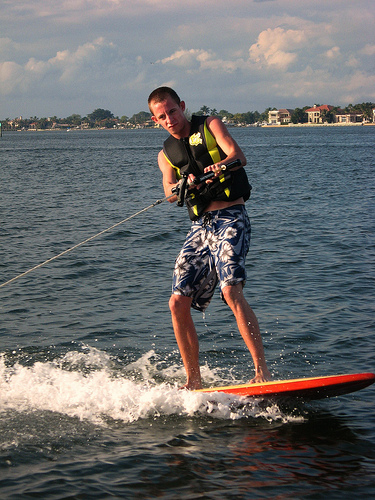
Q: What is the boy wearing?
A: Blue and white shorts.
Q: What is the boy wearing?
A: Life jacket.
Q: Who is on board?
A: A male.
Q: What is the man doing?
A: Pulling a rope.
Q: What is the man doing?
A: A life vest.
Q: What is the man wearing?
A: A short.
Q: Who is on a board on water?
A: A young man.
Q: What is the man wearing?
A: Shorts and a lifejacket.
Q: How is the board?
A: White with red rim.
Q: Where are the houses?
A: On shore far away.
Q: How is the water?
A: Blue.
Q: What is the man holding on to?
A: A handle at the end of a rope.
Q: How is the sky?
A: Blue sky has lot of white clouds.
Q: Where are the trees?
A: On the shore far away.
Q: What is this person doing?
A: Windsurfing.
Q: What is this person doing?
A: Holding onto rope.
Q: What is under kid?
A: Surfboard.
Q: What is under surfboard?
A: Water.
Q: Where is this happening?
A: Ocean.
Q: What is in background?
A: Buildings.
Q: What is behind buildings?
A: Sky.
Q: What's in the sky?
A: Clouds.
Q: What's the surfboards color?
A: Orange.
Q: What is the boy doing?
A: Water skiing.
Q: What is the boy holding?
A: A gray cord.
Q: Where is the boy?
A: On the water.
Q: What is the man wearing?
A: Black vest and yellow stripe.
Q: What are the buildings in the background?
A: Houses.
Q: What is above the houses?
A: Skies with white clouds.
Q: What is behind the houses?
A: Trees in the background.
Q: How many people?
A: 1.